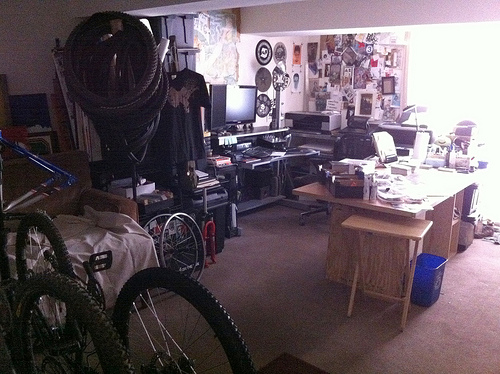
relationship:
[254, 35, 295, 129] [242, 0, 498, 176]
pictures hanging on wall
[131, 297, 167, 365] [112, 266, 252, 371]
metal spoke on tire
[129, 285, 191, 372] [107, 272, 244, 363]
spoke in tire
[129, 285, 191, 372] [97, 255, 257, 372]
spoke in tire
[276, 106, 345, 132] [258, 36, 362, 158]
printer next to wall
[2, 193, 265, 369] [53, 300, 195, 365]
tires has spokes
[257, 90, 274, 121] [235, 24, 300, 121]
sign on wall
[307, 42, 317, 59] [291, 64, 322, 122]
sign on a wall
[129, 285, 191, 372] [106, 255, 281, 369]
spoke on tire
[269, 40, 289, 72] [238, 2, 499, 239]
sign on wall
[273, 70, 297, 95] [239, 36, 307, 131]
sign on wall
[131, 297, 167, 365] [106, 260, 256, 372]
metal spoke on tire